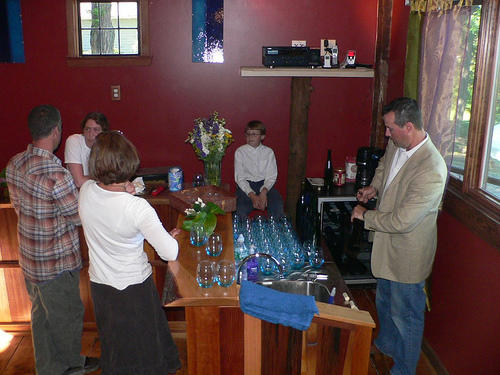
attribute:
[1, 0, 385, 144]
wall — maroon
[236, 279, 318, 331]
cloth — blue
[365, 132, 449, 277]
suit — tan, beige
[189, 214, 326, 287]
glasses — blue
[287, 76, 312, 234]
pole — wooden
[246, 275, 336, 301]
sink — silver